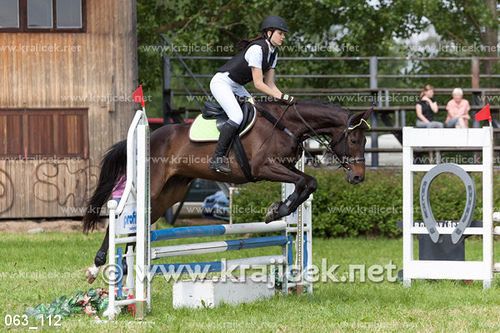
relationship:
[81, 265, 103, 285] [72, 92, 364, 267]
hoof on a horse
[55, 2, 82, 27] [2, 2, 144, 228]
window on building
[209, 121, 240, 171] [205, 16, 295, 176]
boot of rider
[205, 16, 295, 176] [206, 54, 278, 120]
rider wearing pants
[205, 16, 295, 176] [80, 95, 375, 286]
rider riding horse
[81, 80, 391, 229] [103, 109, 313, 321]
horse jumping fence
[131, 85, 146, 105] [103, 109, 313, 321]
flag on fence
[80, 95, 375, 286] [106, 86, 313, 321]
horse jumping fence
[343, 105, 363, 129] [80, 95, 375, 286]
ear on horse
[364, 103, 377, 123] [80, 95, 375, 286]
ear on horse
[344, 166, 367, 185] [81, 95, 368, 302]
mouth on horse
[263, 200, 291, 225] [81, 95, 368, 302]
hoof on horse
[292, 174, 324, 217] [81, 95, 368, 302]
hoof on horse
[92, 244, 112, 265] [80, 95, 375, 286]
hoof on horse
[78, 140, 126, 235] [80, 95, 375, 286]
tail on horse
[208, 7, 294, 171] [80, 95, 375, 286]
rider on horse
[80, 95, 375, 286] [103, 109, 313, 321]
horse jumping fence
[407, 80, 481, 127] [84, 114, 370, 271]
people watching horse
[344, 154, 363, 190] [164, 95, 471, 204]
nose of horse